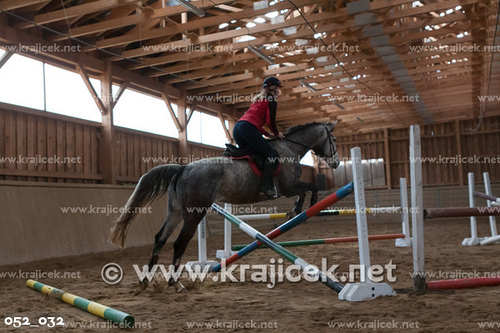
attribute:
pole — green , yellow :
[343, 135, 402, 309]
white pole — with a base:
[338, 144, 397, 304]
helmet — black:
[261, 72, 287, 102]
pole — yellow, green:
[19, 274, 138, 330]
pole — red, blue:
[226, 179, 356, 265]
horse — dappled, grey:
[98, 111, 342, 294]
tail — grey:
[102, 160, 182, 247]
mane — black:
[286, 113, 333, 140]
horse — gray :
[74, 84, 387, 310]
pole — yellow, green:
[33, 250, 160, 328]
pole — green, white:
[268, 245, 303, 280]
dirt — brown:
[250, 292, 307, 324]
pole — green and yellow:
[65, 299, 131, 320]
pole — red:
[425, 275, 458, 302]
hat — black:
[257, 70, 284, 89]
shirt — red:
[234, 86, 275, 136]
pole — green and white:
[230, 224, 312, 282]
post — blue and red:
[285, 198, 329, 229]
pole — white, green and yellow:
[245, 205, 352, 223]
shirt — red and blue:
[227, 83, 270, 136]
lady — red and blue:
[228, 80, 278, 157]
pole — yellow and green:
[7, 280, 124, 326]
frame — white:
[323, 145, 400, 298]